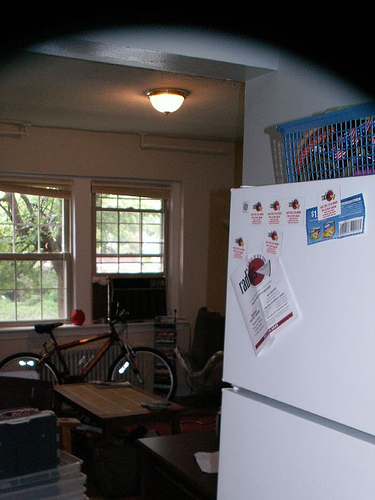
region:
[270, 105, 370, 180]
a blue laundry basket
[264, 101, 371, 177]
a laundry basket on a fridge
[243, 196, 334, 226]
refrigerator magnets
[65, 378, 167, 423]
a wooden table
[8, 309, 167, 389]
a bronze bicycle in a living room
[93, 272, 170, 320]
an air conditioner unit in a window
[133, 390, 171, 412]
two black remotes on a table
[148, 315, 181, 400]
a stack of DVDs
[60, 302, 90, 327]
a red vase on the windowsill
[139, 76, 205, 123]
a light fixture on the ceiling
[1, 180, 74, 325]
Window to the outside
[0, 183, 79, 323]
Trees seen through window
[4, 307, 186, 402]
Red bike inside a house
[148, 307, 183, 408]
CD holding stand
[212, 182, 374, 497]
White refrigerator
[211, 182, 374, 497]
White refrigerator with magnets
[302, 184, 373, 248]
Magnet holding coupon on to fridge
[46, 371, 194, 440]
Wood table with a dark wood frame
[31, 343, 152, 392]
Radiator behind a red bike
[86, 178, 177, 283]
Rolled up window blinds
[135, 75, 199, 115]
Light on the ceiling.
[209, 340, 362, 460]
Door on the refrigerator.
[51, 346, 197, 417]
Table on the floor.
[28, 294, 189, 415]
Bike against the wall.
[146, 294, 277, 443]
CD stand against the wall.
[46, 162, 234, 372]
Windows on the wall.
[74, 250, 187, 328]
Air conditioner on the wall.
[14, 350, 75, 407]
Wheel on the bike.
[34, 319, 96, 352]
Seat on the bike.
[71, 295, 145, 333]
Handles on the bike.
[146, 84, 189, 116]
The light is on.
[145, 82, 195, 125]
The light is dome shaped.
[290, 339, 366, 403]
The fridge is white.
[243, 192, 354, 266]
Six magnets on the fridge.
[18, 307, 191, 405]
Bike in the living room.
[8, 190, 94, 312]
A tree is in the background.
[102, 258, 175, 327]
Air conditioning unit in the window.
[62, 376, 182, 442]
The table is known as a coffee table.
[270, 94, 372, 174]
Laundry basket on top of fridge.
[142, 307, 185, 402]
VHS or DVD holder.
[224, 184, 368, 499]
A white refrigerator.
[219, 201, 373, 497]
Refrigerator with freezer on top.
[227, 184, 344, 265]
Six of the same kind of magnets.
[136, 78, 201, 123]
A light fixture in the ceiling.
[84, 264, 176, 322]
A window air conditioner.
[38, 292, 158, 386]
A radiator under the windows.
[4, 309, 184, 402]
A bicycle against the back wall.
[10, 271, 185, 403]
A man's bicycle.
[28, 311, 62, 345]
Black seat of a bicycle.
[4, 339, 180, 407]
Tires on a bicycle.